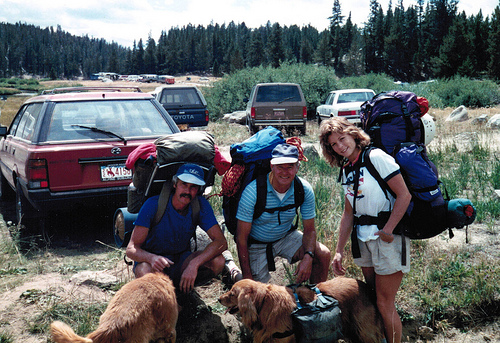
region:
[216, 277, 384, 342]
brown dog with backpack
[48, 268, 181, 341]
the back of a dog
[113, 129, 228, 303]
man with a hiking backpack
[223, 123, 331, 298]
man in middle with hiking backpack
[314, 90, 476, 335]
lady carrying a hiking backpack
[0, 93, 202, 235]
a red station wagon car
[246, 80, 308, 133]
a brown sports utility vehicle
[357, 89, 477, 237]
a big hiking backpack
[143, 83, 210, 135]
a dark colored Toyota truck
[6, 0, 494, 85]
a line of green trees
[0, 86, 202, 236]
a maroon station wagon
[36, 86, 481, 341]
a group of backpackers with dogs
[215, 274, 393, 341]
a golden retriever with an aqua backback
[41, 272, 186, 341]
a golden retriever with its back turned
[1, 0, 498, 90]
a forest of conifers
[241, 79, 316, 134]
a light brown station wagon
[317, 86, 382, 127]
a white sedan car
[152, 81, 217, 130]
a Toyota station wagon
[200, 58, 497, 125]
a patch of green shrubbery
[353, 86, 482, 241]
a mostly blue backpack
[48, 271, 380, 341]
two brown dogs going hiking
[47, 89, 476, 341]
three people and two dogs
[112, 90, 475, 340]
two men and one woman carrying hiking gear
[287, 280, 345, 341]
carrying gear around the dog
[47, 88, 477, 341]
three people going on a hiking adventure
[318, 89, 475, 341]
a young woman carrying blue and black camping gear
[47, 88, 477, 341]
a woman and two men going camping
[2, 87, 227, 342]
a man carrying camping gear behind a red car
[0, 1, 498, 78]
tall green trees in the woods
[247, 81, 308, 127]
a brown mini van parked between two vehicles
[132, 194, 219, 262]
a blue shirton a man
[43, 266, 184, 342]
a golden dog in front of a man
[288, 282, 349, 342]
a gray bag on a dog's back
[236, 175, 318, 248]
a blue shirt with white stripes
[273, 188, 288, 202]
a white undershirt on a man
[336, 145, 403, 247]
a white shirt on woman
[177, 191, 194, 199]
a moustache on a man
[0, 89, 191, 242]
a red station wagon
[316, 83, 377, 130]
a white car behind a woman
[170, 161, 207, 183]
a blue cap on a man's head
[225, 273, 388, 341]
a golden dog with a backpack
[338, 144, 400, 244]
a white shirt on a woman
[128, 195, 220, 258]
a blue shirt on a man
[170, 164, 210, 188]
a blue cap on a man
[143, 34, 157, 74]
a green pine tree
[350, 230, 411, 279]
tan shorts on a woman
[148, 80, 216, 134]
a Toyota pickup truck with a camper top